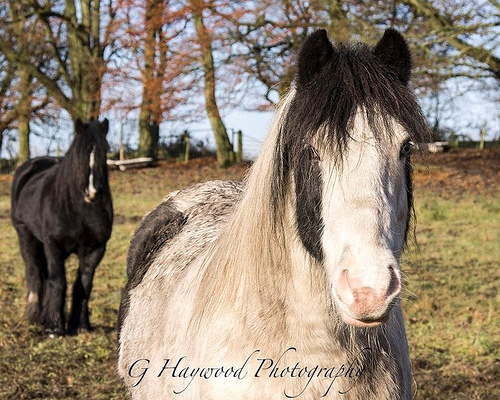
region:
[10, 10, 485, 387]
2 horses in a field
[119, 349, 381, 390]
a photographer watermark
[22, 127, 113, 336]
a large black horse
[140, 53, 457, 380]
a large black and white horse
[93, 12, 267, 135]
trees shedding their leaves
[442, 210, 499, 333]
dry grass in a field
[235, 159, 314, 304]
a grey horses main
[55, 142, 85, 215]
a black horses mane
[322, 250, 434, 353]
a white horse's nose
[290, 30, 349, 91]
a black horse's ear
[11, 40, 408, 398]
A pair of horses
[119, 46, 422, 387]
A white horse with black markings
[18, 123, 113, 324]
a black horse with white markings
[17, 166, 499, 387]
a grassy field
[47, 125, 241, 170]
A fence behind some trees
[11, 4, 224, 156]
A small group of trees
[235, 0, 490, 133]
Some trees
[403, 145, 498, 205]
some leaves on the ground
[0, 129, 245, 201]
some leaves on the ground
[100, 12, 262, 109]
leaves on the trees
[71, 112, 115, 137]
The ears of the black horse.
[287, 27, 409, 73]
The ears of the black and white horse.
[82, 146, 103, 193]
White marking on the black horse's face.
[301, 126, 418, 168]
The eyes of the black and white horse.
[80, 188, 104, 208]
The nose of the black horse.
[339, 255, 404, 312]
The nose and nostrils of the black and white horse.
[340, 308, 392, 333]
The mouth of the black and white horse.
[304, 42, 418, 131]
The black mane on the black and white horse's head.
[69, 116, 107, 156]
The mane on the black horse's head.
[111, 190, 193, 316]
The black fur on the white horse's back.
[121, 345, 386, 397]
Photographer's black logo at the bottom of the photo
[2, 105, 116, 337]
Black horse with white stripe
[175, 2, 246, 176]
Brown tree in background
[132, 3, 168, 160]
Brown tree in background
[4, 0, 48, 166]
Brown tree in background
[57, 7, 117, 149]
Brown trees in background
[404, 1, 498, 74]
Branch of a brown tree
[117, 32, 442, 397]
Black and white horse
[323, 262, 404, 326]
Horse's pink nose and mouth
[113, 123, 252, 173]
Fence in background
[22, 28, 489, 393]
two horses in photograph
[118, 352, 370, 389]
black writing on bottom of photograph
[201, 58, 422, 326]
horse has white and black mane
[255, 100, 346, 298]
horse has black on right side of face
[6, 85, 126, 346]
black horse in photograph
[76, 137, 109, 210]
one white line on horses face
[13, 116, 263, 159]
fence in background of photo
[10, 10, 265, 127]
trees with autumn colored leaves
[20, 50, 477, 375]
one horse standing behind another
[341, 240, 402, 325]
pink spot on horse's snout